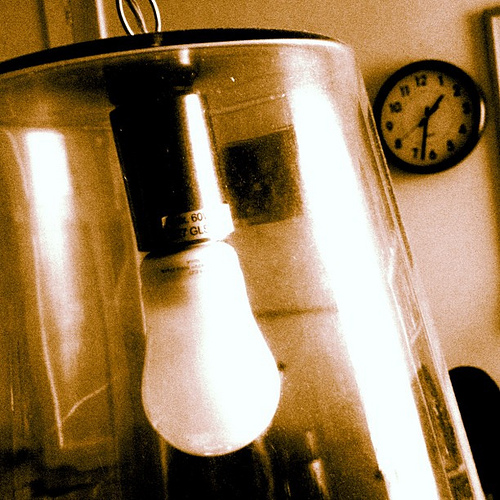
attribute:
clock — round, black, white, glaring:
[370, 59, 487, 175]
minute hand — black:
[420, 108, 432, 160]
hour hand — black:
[425, 91, 444, 123]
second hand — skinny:
[395, 115, 425, 146]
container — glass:
[2, 34, 487, 500]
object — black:
[447, 368, 497, 500]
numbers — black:
[384, 73, 473, 162]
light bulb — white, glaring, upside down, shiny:
[141, 243, 285, 455]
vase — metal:
[285, 436, 331, 499]